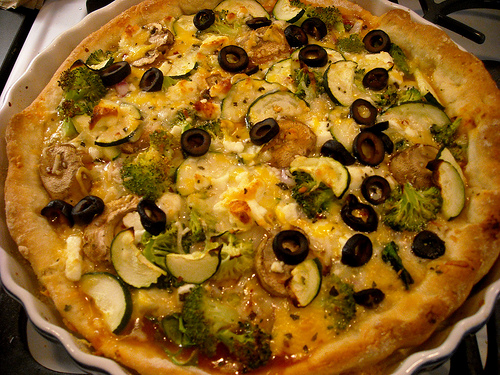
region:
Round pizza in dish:
[6, 0, 498, 374]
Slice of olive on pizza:
[336, 230, 370, 266]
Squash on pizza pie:
[283, 260, 320, 305]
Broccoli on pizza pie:
[120, 147, 167, 196]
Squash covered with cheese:
[172, 153, 257, 207]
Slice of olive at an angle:
[247, 117, 282, 143]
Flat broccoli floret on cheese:
[384, 183, 444, 230]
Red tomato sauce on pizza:
[139, 333, 299, 369]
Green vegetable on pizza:
[384, 240, 415, 290]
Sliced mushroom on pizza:
[141, 21, 172, 66]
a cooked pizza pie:
[7, 5, 484, 366]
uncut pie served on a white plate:
[11, 5, 496, 362]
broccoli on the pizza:
[185, 282, 267, 352]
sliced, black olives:
[270, 221, 310, 266]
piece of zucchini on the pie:
[105, 230, 161, 295]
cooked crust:
[0, 107, 40, 254]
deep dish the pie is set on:
[0, 247, 45, 337]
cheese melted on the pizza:
[187, 160, 269, 215]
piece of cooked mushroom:
[40, 145, 77, 192]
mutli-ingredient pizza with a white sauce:
[18, 7, 484, 360]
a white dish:
[0, 2, 499, 374]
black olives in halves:
[44, 4, 446, 309]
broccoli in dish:
[61, 10, 418, 355]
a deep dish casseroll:
[9, 3, 499, 360]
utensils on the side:
[423, 3, 486, 45]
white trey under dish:
[3, 0, 490, 372]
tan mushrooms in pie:
[35, 23, 435, 293]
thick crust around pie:
[5, 1, 494, 373]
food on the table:
[3, 3, 498, 370]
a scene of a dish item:
[3, 2, 494, 373]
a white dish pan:
[2, 1, 493, 371]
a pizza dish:
[0, 1, 471, 368]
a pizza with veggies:
[5, 12, 497, 344]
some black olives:
[22, 49, 493, 349]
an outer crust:
[16, 31, 488, 371]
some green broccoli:
[3, 15, 490, 333]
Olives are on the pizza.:
[170, 124, 218, 159]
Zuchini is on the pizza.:
[275, 247, 326, 334]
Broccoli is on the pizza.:
[386, 174, 438, 241]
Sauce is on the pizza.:
[125, 302, 309, 373]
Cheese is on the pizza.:
[78, 56, 445, 322]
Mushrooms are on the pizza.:
[261, 116, 300, 157]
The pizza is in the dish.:
[3, 4, 492, 366]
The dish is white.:
[7, 9, 489, 374]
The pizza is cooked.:
[27, 19, 477, 374]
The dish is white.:
[16, 8, 488, 373]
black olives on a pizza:
[349, 100, 388, 163]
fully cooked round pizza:
[3, 4, 499, 374]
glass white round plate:
[3, 3, 498, 372]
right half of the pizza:
[242, 0, 499, 374]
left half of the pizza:
[1, 3, 261, 372]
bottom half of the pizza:
[6, 149, 497, 374]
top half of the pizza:
[6, 3, 498, 163]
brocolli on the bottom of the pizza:
[168, 285, 258, 362]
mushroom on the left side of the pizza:
[39, 138, 85, 197]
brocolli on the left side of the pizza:
[53, 65, 108, 127]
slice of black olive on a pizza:
[272, 230, 308, 264]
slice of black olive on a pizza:
[341, 234, 371, 264]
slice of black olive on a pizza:
[411, 228, 443, 257]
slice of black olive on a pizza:
[341, 193, 376, 230]